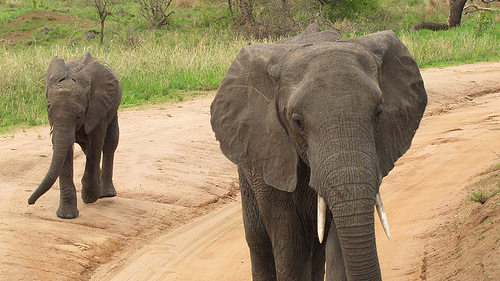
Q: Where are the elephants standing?
A: In the road.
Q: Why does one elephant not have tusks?
A: It is not fully grown.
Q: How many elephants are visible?
A: Two.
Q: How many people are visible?
A: None.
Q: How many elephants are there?
A: Two.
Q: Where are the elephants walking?
A: In the dirt.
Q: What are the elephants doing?
A: Walking.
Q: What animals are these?
A: Elephants.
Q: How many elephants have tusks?
A: One.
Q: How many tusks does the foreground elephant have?
A: Two.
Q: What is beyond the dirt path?
A: Grass.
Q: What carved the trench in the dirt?
A: Water.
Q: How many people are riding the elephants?
A: None.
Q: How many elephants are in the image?
A: 2.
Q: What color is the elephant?
A: Brown.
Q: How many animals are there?
A: Two.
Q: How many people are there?
A: Zero.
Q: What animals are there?
A: Elephants.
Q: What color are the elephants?
A: Gray.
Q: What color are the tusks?
A: Ivory.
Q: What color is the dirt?
A: Tan.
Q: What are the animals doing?
A: Walking.